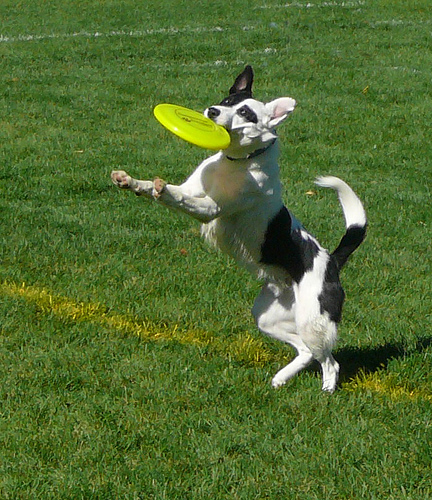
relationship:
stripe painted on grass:
[0, 261, 431, 407] [34, 41, 164, 88]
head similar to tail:
[206, 65, 296, 148] [313, 175, 369, 270]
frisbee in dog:
[155, 105, 234, 149] [111, 68, 365, 393]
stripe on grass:
[0, 261, 429, 405] [0, 0, 432, 483]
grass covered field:
[28, 340, 246, 462] [2, 2, 428, 494]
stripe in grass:
[0, 261, 431, 407] [0, 0, 432, 483]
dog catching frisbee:
[111, 68, 365, 393] [149, 100, 233, 153]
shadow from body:
[328, 324, 430, 386] [218, 157, 341, 336]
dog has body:
[111, 68, 365, 393] [218, 157, 341, 336]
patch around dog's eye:
[229, 101, 263, 130] [237, 107, 249, 117]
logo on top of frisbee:
[172, 109, 201, 131] [150, 101, 229, 148]